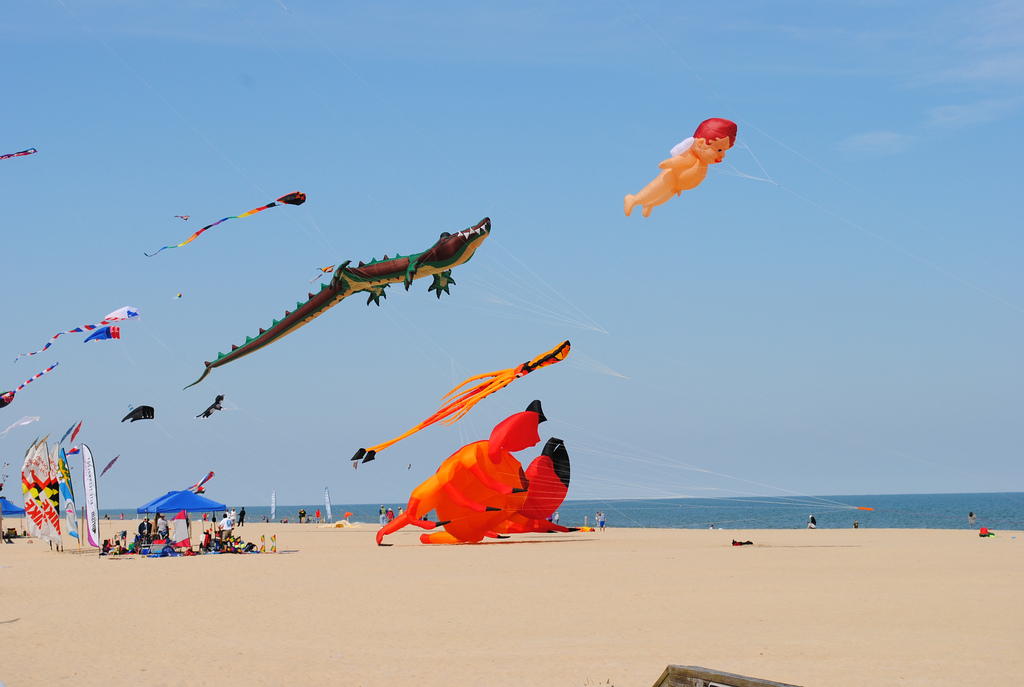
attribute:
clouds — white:
[819, 77, 1006, 169]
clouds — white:
[572, 315, 646, 398]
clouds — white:
[723, 8, 1021, 161]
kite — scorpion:
[366, 388, 585, 559]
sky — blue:
[0, 5, 1024, 505]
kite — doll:
[627, 116, 738, 235]